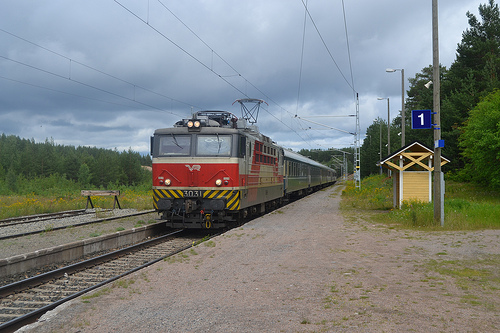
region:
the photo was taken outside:
[3, 2, 493, 328]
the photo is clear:
[7, 2, 498, 318]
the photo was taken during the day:
[7, 2, 497, 330]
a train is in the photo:
[116, 101, 383, 247]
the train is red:
[131, 107, 361, 242]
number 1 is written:
[402, 104, 468, 168]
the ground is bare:
[277, 219, 440, 330]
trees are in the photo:
[11, 142, 139, 194]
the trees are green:
[6, 138, 142, 200]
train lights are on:
[161, 160, 246, 228]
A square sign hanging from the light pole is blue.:
[408, 107, 434, 133]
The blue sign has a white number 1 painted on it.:
[417, 110, 425, 127]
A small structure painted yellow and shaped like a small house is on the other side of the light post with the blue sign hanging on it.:
[374, 135, 454, 211]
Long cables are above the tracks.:
[0, 0, 373, 195]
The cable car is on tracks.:
[3, 167, 343, 331]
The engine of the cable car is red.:
[143, 107, 288, 234]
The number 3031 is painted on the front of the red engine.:
[179, 187, 204, 199]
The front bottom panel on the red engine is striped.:
[150, 186, 238, 211]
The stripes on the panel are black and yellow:
[150, 186, 240, 212]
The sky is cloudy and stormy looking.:
[0, 0, 498, 160]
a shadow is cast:
[145, 216, 197, 249]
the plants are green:
[428, 68, 485, 153]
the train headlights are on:
[149, 87, 289, 261]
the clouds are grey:
[56, 21, 143, 96]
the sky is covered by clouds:
[28, 13, 211, 96]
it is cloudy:
[1, 6, 441, 294]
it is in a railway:
[12, 10, 351, 273]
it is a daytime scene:
[7, 6, 468, 326]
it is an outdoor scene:
[13, 11, 465, 319]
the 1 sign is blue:
[409, 78, 459, 170]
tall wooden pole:
[421, 0, 459, 229]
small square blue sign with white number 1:
[406, 106, 436, 133]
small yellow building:
[376, 117, 452, 222]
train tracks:
[2, 227, 193, 282]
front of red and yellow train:
[147, 122, 251, 213]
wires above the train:
[91, 2, 389, 115]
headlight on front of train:
[159, 165, 236, 192]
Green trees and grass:
[446, 0, 497, 229]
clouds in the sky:
[6, 7, 138, 159]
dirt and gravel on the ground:
[228, 230, 436, 332]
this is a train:
[149, 116, 296, 219]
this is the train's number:
[184, 187, 203, 199]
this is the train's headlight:
[214, 178, 221, 188]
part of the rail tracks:
[9, 264, 81, 306]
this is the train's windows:
[157, 128, 229, 157]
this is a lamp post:
[386, 66, 407, 146]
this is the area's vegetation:
[11, 139, 128, 184]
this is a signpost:
[411, 105, 433, 131]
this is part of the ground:
[285, 250, 395, 329]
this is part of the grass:
[361, 186, 385, 203]